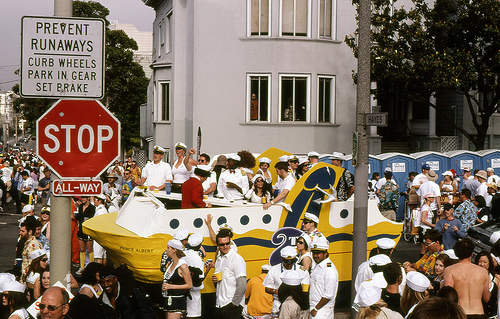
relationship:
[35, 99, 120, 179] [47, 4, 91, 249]
stop sign on pole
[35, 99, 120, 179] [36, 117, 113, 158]
stop sign says stop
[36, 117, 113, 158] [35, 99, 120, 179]
stop on stop sign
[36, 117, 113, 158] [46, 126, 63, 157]
stop has s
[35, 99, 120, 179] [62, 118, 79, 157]
stop sign has t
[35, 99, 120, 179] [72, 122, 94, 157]
stop sign has o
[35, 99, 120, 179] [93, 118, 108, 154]
stop sign has p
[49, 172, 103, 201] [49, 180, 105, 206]
sign says all-way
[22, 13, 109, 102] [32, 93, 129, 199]
sign above stop sign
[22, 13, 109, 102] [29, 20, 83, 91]
sign has word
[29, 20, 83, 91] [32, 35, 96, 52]
word says runaways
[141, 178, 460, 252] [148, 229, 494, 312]
parade has people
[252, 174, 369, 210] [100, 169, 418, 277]
people on float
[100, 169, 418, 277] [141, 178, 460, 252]
float in parade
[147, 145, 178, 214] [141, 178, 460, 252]
captain at parade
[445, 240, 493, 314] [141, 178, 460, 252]
man at parade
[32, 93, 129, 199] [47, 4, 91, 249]
stop sign attached to pole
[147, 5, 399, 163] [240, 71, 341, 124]
building has windows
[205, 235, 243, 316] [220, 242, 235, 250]
person wearing glasses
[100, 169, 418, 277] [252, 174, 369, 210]
float has people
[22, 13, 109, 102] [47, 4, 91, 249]
sign on pole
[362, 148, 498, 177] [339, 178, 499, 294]
portables behind crowd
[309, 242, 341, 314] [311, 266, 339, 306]
person has shirt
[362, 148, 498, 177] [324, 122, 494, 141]
portapotties on side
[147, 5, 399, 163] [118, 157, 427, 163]
building on road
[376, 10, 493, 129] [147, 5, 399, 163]
tree by building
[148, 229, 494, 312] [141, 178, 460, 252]
people at parade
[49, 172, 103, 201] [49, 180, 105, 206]
sign reads all-way